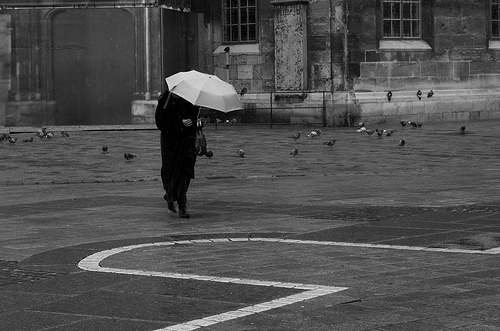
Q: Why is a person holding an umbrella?
A: It is raining.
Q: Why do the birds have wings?
A: To be able to fly.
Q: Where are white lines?
A: On the ground.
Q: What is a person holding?
A: Umbrella.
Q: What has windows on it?
A: A building.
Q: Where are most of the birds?
A: On the ground.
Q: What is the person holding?
A: An umbrella.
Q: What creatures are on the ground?
A: Birds.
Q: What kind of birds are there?
A: Pigeons.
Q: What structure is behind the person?
A: A building.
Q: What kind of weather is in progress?
A: It is raining.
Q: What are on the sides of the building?
A: Windows.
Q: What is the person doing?
A: Walking.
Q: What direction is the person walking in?
A: Towards the camera.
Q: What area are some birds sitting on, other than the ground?
A: Side of the building.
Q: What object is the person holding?
A: An umbrella.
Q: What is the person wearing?
A: All black.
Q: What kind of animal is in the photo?
A: Birds.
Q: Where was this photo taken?
A: In a lot.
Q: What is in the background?
A: A building.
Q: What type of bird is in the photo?
A: Pigeon.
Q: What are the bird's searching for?
A: Food.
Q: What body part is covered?
A: Face.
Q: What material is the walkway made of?
A: Cement.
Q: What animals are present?
A: Birds.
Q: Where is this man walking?
A: On a street.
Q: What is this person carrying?
A: Umbrella.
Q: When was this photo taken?
A: During the day.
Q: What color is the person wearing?
A: Black.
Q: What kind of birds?
A: Pigeons.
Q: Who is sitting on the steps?
A: No one.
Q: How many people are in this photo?
A: 1.